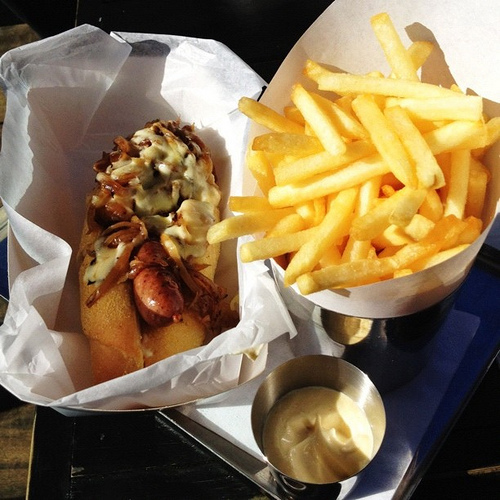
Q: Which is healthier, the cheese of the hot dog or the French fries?
A: The cheese is healthier than the French fries.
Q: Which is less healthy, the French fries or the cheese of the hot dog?
A: The French fries is less healthy than the cheese.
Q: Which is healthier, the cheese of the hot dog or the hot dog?
A: The cheese is healthier than the hot dog.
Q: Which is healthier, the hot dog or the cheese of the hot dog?
A: The cheese is healthier than the hot dog.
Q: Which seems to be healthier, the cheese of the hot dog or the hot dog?
A: The cheese is healthier than the hot dog.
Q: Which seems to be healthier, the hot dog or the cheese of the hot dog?
A: The cheese is healthier than the hot dog.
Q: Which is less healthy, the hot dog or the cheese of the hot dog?
A: The hot dog is less healthy than the cheese.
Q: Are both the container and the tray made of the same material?
A: Yes, both the container and the tray are made of metal.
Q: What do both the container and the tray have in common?
A: The material, both the container and the tray are metallic.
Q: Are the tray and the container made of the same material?
A: Yes, both the tray and the container are made of metal.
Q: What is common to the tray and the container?
A: The material, both the tray and the container are metallic.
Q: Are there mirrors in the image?
A: No, there are no mirrors.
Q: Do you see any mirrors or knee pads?
A: No, there are no mirrors or knee pads.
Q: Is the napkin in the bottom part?
A: Yes, the napkin is in the bottom of the image.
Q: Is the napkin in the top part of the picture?
A: No, the napkin is in the bottom of the image.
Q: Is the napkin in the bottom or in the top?
A: The napkin is in the bottom of the image.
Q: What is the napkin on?
A: The napkin is on the tray.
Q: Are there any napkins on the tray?
A: Yes, there is a napkin on the tray.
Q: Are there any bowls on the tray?
A: No, there is a napkin on the tray.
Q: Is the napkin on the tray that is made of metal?
A: Yes, the napkin is on the tray.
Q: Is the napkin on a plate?
A: No, the napkin is on the tray.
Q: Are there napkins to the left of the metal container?
A: Yes, there is a napkin to the left of the container.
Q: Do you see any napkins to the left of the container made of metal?
A: Yes, there is a napkin to the left of the container.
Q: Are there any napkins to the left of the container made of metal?
A: Yes, there is a napkin to the left of the container.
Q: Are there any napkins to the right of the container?
A: No, the napkin is to the left of the container.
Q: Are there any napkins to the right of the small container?
A: No, the napkin is to the left of the container.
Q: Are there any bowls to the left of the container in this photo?
A: No, there is a napkin to the left of the container.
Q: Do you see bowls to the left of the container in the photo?
A: No, there is a napkin to the left of the container.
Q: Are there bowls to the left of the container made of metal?
A: No, there is a napkin to the left of the container.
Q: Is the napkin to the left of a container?
A: Yes, the napkin is to the left of a container.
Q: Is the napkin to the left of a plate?
A: No, the napkin is to the left of a container.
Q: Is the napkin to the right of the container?
A: No, the napkin is to the left of the container.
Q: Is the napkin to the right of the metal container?
A: No, the napkin is to the left of the container.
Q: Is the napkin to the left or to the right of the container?
A: The napkin is to the left of the container.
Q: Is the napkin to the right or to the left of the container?
A: The napkin is to the left of the container.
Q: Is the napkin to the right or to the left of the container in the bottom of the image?
A: The napkin is to the left of the container.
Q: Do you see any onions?
A: Yes, there is an onion.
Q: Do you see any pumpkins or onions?
A: Yes, there is an onion.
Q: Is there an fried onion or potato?
A: Yes, there is a fried onion.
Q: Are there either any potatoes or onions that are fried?
A: Yes, the onion is fried.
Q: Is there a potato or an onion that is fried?
A: Yes, the onion is fried.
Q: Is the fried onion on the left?
A: Yes, the onion is on the left of the image.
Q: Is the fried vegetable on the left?
A: Yes, the onion is on the left of the image.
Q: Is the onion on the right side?
A: No, the onion is on the left of the image.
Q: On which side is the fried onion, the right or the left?
A: The onion is on the left of the image.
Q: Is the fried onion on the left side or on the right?
A: The onion is on the left of the image.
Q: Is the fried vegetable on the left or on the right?
A: The onion is on the left of the image.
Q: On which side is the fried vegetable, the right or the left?
A: The onion is on the left of the image.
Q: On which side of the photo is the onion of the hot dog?
A: The onion is on the left of the image.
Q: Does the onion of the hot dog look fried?
A: Yes, the onion is fried.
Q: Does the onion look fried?
A: Yes, the onion is fried.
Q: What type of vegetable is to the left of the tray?
A: The vegetable is an onion.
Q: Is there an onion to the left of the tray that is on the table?
A: Yes, there is an onion to the left of the tray.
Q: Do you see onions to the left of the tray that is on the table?
A: Yes, there is an onion to the left of the tray.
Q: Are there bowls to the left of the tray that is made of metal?
A: No, there is an onion to the left of the tray.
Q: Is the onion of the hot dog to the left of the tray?
A: Yes, the onion is to the left of the tray.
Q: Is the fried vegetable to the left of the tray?
A: Yes, the onion is to the left of the tray.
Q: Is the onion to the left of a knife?
A: No, the onion is to the left of the tray.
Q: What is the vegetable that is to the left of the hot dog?
A: The vegetable is an onion.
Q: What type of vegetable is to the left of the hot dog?
A: The vegetable is an onion.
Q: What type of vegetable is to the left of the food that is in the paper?
A: The vegetable is an onion.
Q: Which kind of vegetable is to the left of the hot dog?
A: The vegetable is an onion.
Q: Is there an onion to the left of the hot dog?
A: Yes, there is an onion to the left of the hot dog.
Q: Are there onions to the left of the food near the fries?
A: Yes, there is an onion to the left of the hot dog.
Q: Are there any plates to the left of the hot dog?
A: No, there is an onion to the left of the hot dog.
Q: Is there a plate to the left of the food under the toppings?
A: No, there is an onion to the left of the hot dog.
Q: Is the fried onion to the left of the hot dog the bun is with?
A: Yes, the onion is to the left of the hot dog.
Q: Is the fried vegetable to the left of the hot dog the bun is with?
A: Yes, the onion is to the left of the hot dog.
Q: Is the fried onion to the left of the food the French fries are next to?
A: Yes, the onion is to the left of the hot dog.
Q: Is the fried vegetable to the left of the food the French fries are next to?
A: Yes, the onion is to the left of the hot dog.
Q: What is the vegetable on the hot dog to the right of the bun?
A: The vegetable is an onion.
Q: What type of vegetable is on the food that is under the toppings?
A: The vegetable is an onion.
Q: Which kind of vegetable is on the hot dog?
A: The vegetable is an onion.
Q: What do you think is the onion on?
A: The onion is on the hot dog.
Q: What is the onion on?
A: The onion is on the hot dog.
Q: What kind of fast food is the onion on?
A: The onion is on the hot dog.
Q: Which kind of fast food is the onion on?
A: The onion is on the hot dog.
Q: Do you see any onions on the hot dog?
A: Yes, there is an onion on the hot dog.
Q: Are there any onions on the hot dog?
A: Yes, there is an onion on the hot dog.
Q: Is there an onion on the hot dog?
A: Yes, there is an onion on the hot dog.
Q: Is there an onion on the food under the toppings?
A: Yes, there is an onion on the hot dog.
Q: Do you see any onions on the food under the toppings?
A: Yes, there is an onion on the hot dog.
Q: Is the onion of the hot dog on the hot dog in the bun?
A: Yes, the onion is on the hot dog.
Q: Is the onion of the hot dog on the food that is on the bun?
A: Yes, the onion is on the hot dog.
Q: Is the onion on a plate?
A: No, the onion is on the hot dog.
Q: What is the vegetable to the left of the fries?
A: The vegetable is an onion.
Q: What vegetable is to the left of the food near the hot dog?
A: The vegetable is an onion.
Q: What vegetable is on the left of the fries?
A: The vegetable is an onion.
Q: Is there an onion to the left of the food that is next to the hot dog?
A: Yes, there is an onion to the left of the French fries.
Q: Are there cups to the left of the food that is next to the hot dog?
A: No, there is an onion to the left of the fries.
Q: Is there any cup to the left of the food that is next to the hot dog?
A: No, there is an onion to the left of the fries.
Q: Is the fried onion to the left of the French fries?
A: Yes, the onion is to the left of the French fries.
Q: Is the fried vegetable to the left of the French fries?
A: Yes, the onion is to the left of the French fries.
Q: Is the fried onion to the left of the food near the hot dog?
A: Yes, the onion is to the left of the French fries.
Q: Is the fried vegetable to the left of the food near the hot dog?
A: Yes, the onion is to the left of the French fries.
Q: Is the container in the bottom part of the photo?
A: Yes, the container is in the bottom of the image.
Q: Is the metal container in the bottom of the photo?
A: Yes, the container is in the bottom of the image.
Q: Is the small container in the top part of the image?
A: No, the container is in the bottom of the image.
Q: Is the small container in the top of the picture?
A: No, the container is in the bottom of the image.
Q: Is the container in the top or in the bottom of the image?
A: The container is in the bottom of the image.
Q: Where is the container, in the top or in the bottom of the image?
A: The container is in the bottom of the image.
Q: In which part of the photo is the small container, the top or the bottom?
A: The container is in the bottom of the image.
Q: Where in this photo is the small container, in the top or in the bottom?
A: The container is in the bottom of the image.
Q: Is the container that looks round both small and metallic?
A: Yes, the container is small and metallic.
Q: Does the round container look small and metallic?
A: Yes, the container is small and metallic.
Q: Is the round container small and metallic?
A: Yes, the container is small and metallic.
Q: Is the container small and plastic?
A: No, the container is small but metallic.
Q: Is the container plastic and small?
A: No, the container is small but metallic.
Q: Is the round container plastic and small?
A: No, the container is small but metallic.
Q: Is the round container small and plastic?
A: No, the container is small but metallic.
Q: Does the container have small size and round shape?
A: Yes, the container is small and round.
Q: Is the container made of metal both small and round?
A: Yes, the container is small and round.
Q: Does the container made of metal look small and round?
A: Yes, the container is small and round.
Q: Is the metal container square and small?
A: No, the container is small but round.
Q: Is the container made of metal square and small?
A: No, the container is small but round.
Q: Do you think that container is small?
A: Yes, the container is small.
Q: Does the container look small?
A: Yes, the container is small.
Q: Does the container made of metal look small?
A: Yes, the container is small.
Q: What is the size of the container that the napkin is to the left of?
A: The container is small.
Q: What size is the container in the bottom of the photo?
A: The container is small.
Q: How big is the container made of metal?
A: The container is small.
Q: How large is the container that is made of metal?
A: The container is small.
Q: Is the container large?
A: No, the container is small.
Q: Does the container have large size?
A: No, the container is small.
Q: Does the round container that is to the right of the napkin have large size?
A: No, the container is small.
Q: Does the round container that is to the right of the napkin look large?
A: No, the container is small.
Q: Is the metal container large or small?
A: The container is small.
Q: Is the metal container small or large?
A: The container is small.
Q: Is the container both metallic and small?
A: Yes, the container is metallic and small.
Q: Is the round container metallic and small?
A: Yes, the container is metallic and small.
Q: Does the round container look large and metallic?
A: No, the container is metallic but small.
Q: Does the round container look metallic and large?
A: No, the container is metallic but small.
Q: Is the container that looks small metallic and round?
A: Yes, the container is metallic and round.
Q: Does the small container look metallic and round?
A: Yes, the container is metallic and round.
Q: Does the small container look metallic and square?
A: No, the container is metallic but round.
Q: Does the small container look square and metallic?
A: No, the container is metallic but round.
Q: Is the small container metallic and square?
A: No, the container is metallic but round.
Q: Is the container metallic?
A: Yes, the container is metallic.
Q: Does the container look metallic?
A: Yes, the container is metallic.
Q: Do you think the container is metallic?
A: Yes, the container is metallic.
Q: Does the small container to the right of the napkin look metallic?
A: Yes, the container is metallic.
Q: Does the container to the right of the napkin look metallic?
A: Yes, the container is metallic.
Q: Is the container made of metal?
A: Yes, the container is made of metal.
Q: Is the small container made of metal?
A: Yes, the container is made of metal.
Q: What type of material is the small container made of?
A: The container is made of metal.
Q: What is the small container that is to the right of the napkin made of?
A: The container is made of metal.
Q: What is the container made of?
A: The container is made of metal.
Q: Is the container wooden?
A: No, the container is metallic.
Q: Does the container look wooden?
A: No, the container is metallic.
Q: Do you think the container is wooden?
A: No, the container is metallic.